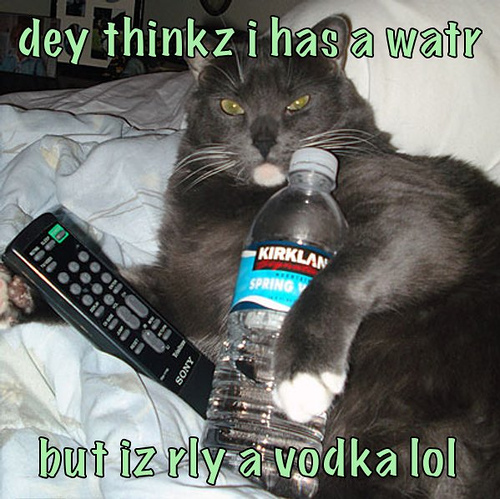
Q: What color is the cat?
A: Gray.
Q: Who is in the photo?
A: The cat.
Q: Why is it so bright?
A: Lights are on.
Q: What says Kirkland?
A: Water bottle.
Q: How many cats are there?
A: One.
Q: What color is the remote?
A: Black.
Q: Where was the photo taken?
A: The picture was taken in a bed.